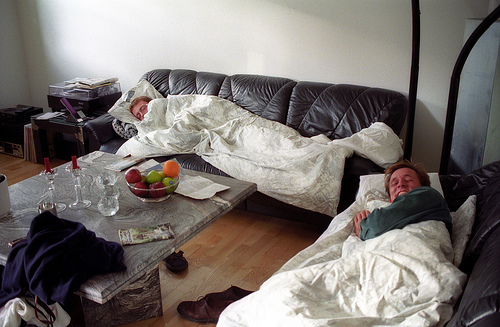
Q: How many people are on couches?
A: 2.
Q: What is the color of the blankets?
A: White.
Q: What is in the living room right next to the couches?
A: Table.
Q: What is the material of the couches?
A: Leather.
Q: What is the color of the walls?
A: White.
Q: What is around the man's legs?
A: Sheet.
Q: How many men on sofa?
A: 2.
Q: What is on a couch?
A: A man.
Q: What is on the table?
A: Bowl.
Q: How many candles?
A: 2.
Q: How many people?
A: 2.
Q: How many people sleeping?
A: 2.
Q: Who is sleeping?
A: A man.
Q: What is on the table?
A: Clothes.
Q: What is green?
A: Shirt.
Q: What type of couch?
A: Leather.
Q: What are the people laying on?
A: Couches.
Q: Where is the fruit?
A: In the bowl.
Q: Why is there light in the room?
A: It is natural light.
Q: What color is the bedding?
A: White.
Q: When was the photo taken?
A: Daytime.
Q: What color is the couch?
A: Gray.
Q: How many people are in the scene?
A: Two.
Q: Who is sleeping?
A: A man.